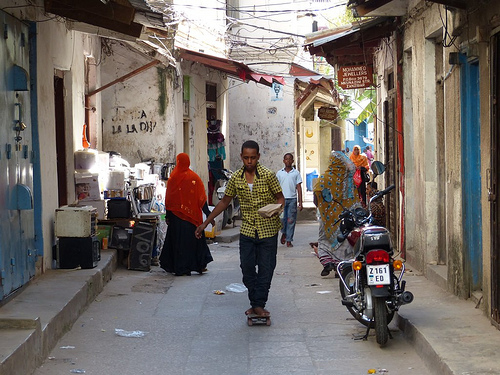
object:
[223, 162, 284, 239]
shirt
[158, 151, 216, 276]
woman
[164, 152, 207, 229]
scarf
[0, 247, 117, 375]
sidewalk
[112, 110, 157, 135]
graffiti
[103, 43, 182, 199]
wall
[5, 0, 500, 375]
street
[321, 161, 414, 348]
bike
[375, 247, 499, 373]
sidewalk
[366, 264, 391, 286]
plate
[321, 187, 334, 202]
mirror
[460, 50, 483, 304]
door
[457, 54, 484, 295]
trim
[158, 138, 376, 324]
people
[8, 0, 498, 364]
area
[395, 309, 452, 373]
curb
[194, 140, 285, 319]
kid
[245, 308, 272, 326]
skateboard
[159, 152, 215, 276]
lady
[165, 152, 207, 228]
orange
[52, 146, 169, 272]
pile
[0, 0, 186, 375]
building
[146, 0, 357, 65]
wires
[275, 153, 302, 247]
man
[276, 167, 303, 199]
shirt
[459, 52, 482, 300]
doorway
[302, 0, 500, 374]
building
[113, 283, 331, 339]
trash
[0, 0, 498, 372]
alley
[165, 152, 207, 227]
fabric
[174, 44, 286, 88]
awning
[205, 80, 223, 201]
doorway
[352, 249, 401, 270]
lights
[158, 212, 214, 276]
dress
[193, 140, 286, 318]
boy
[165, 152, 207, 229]
jihab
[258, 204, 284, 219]
book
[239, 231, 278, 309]
pants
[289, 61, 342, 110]
roof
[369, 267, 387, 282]
z161 ed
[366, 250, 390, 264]
stoplight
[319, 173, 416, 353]
motorcycle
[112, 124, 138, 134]
la la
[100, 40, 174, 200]
side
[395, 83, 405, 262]
pole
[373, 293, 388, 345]
tire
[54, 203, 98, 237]
box